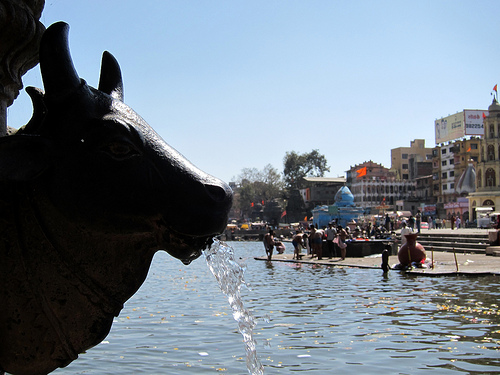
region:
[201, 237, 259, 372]
water spilling out of the mouth of the statue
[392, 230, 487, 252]
four concrete steps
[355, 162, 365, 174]
bright orange flag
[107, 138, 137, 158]
eye of the bull statue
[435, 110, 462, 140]
yellow banner on top of the building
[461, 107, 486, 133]
white banner on top of the building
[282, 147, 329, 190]
tall green tree in the distance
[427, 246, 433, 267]
short yellow pole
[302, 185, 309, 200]
small orange section of building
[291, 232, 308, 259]
man near water bending over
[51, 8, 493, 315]
water activity next to the city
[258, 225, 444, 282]
people are playing near the water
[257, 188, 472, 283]
there might be a festival going on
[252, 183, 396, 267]
this public event looks busy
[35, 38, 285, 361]
this statue is spitting water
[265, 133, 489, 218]
buildings along the shoreline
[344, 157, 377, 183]
an orange flag flying above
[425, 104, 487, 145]
some kind of billboard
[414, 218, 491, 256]
stairs leading to the dock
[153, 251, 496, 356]
the water looks clear and blue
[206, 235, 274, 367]
a stream of water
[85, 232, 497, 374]
the water is blue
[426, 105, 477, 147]
yellow billboard on top of building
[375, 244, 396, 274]
statue near the water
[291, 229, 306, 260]
statue near the water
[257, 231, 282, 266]
statue near the water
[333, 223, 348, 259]
person near the water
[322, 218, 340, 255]
person near the water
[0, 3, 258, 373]
black statue near the water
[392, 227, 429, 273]
statue near the water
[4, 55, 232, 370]
statue of a bull spitting water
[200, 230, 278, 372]
fountain of water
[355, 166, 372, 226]
bright orange flag on a pole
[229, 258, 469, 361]
large pool of water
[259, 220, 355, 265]
people standing near the water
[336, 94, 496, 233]
group of short and tall buildings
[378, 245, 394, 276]
person standing in the water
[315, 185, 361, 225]
light blue building with a pointed top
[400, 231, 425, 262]
huge red hued vase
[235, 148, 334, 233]
group of trees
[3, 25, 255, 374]
THE FOUNTAIN IS A GOAT HEAD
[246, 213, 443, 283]
THE CROWD IS AT THE WATER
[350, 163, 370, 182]
THE FLAG IS ORANGE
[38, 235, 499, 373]
THE WATER IS REFLECTING LIGHT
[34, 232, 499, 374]
THE WATER IS REFLECTING THE BLUE SKY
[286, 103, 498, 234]
THE BUILDINGS ARE TALL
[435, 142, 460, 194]
THE BUILDING HAS MANY WINDOWS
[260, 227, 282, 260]
THE MAN IS ON THE SIDE OF THE WATER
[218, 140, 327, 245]
THE TREES ARE TALL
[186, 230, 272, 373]
THE WATER IS COMING OUT OF THE OX'S NOSE